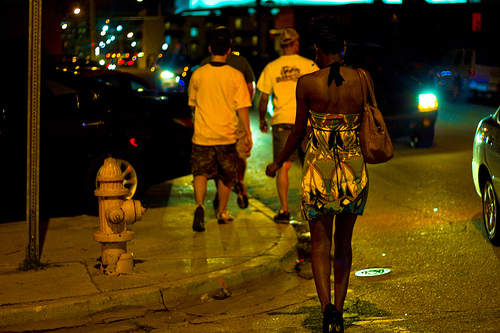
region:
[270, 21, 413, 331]
this is a woman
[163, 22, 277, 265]
this is a man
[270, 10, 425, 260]
woman wearing a dress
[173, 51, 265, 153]
man wearing a white shirt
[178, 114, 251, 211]
man wearing a pair of shorts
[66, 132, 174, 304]
this is a fire hydrant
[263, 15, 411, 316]
woman walking on the street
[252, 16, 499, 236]
cars on the street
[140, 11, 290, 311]
man on the sidewalk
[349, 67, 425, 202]
woman carrying a purse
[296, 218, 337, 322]
leg of a person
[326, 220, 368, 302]
leg of a person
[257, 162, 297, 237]
leg of a person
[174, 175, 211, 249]
leg of a person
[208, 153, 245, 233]
leg of a person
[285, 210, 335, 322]
a leg of a person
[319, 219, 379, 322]
a leg of a person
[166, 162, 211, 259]
a leg of a person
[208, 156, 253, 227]
a leg of a person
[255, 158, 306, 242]
a leg of a person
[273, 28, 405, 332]
Woman walking in the street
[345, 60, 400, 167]
Purse on the woman's shoulder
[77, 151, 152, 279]
Fire hydrant on the sidewalk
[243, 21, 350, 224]
Man wearing a white shirt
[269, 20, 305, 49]
Hat on the man's head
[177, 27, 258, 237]
Man wearing a white shirt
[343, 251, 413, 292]
Drain on the ground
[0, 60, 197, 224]
Car near the sidewalk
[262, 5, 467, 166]
Truck on the street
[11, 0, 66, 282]
Pole on the sidewalk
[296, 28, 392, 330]
A woman in a green and yellow sundress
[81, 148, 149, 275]
A yellow fire hydrant on a street corner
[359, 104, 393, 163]
A brown leather purse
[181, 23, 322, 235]
Two men in shorts walking down a city street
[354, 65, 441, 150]
The headlight on a car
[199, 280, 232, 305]
Trash at the side of a curb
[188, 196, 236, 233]
Black sandals on a man's feet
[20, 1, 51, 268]
A metal signpost next to a fire hydrant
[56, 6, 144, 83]
City lights in the distance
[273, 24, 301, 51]
A baseball cap on a man's head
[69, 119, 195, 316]
a fire hydrant on the sidewalk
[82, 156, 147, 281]
a hydrant on the sidewalk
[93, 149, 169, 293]
a yellow fire hydrant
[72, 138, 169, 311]
a yellow fire hydrant on the sidewalk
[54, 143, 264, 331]
a yellow hydrant on the sidewalk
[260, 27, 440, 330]
a woman walking on the road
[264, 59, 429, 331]
a woman walking on the street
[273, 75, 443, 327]
a woman wearing a dress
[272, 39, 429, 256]
a woman carrying a bag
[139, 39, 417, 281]
people walking on the sidewalk